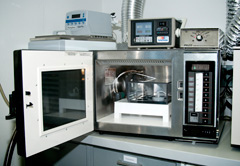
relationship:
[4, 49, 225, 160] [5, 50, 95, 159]
oven has door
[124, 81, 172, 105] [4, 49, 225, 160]
container inside oven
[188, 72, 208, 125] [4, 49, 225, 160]
buttons on oven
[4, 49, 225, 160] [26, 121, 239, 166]
oven on stand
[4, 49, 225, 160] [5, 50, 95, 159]
microwave has door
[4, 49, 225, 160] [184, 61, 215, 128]
microwave has control panel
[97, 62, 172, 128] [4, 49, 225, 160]
inside of microwave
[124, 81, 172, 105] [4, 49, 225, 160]
dish in microwave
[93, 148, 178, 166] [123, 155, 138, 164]
drawer has label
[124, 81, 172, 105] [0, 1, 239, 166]
container in laboratory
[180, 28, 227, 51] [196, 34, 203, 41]
monitor has dial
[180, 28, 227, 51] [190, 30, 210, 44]
monitor has numbers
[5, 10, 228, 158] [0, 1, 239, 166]
lab equipment in laboratory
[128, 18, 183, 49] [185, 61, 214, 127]
device on top of microwave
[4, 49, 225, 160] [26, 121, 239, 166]
microwave on stand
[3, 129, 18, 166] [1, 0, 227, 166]
pipe next to wall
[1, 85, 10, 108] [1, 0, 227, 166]
pipe next to wall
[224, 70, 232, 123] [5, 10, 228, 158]
power cord behind lab equipment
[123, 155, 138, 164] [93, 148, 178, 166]
label on drawer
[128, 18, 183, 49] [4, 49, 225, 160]
monitoring device on top of oven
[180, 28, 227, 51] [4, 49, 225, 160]
electronic device on top of oven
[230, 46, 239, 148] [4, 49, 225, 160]
box next to oven